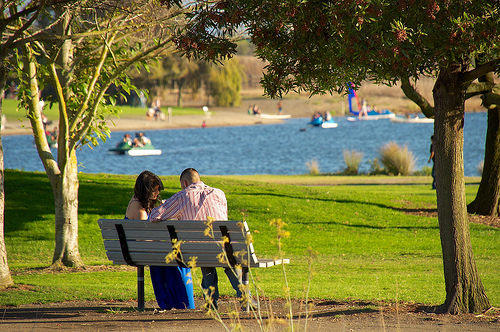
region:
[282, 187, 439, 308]
Green grassy terrain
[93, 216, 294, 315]
Light wooded park bench.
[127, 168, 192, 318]
Brunette wearing blue dress.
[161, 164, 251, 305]
Man wearing button up dress shirt.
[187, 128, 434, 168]
blue calm body of water.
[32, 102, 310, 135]
sandy beach in background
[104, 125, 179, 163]
People on a raft.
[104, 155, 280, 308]
Man and woman sitting together on bench.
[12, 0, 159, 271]
Large tree in park.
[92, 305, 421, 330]
grassless dirt terrain.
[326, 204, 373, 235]
green grass on the ground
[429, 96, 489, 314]
tree bark in dirt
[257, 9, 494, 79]
branches on the tree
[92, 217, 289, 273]
white park bench outside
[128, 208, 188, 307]
blue dress on the woman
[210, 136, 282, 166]
blue body of water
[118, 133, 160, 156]
group of people riding in boat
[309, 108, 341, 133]
group riding in a boat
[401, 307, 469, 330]
brown dirt on the ground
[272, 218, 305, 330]
tall weeds growing from ground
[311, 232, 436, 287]
sunshine on a green park lawn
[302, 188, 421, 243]
Shadows from tree branches on the grass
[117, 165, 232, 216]
A man and a woman conversing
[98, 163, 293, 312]
A man and woman sitting on a park bench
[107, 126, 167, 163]
A row boat in the distance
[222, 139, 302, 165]
Ripley blue water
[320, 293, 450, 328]
A brown sandy walkway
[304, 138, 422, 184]
Bushes along the water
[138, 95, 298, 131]
People on the beach in the distance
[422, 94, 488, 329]
A brown tree trunk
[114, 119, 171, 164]
white boat in water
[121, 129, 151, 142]
people sitting on the boat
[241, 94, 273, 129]
people sitting on shore line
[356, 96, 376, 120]
person standing on boat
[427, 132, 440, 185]
man walking on the path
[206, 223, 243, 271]
black brackets on bench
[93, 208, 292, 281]
large wooden brown bench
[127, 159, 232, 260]
people sitting on bench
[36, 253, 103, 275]
brown dirt around crown of tree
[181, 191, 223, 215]
red and white stripe shirt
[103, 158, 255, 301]
two people sitting on a park bench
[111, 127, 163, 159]
some people in a small boat on water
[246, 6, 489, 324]
a small tree with some red flowering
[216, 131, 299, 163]
some clear blue water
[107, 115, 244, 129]
some sand in the distance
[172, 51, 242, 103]
a hung over willow tree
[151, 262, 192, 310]
a blue dress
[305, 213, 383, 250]
some very short green grass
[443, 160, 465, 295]
some tree bark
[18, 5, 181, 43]
some tree branches